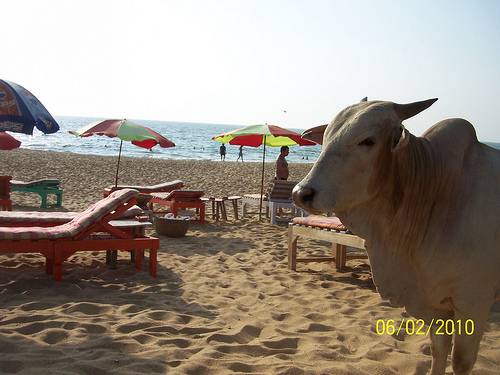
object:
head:
[291, 96, 439, 215]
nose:
[291, 183, 315, 213]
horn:
[397, 98, 439, 121]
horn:
[299, 124, 327, 148]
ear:
[389, 123, 411, 154]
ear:
[299, 124, 328, 147]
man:
[274, 145, 290, 182]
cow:
[288, 97, 500, 375]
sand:
[0, 146, 500, 375]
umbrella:
[211, 122, 318, 220]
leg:
[449, 294, 496, 375]